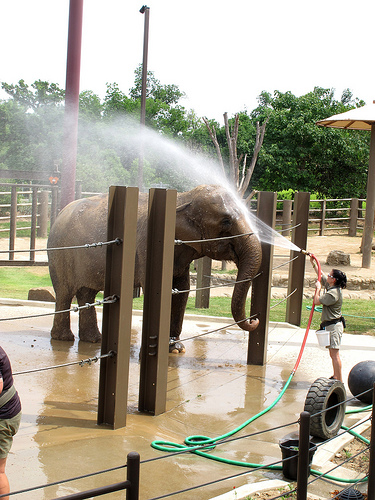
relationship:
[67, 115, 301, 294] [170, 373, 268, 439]
water on ground